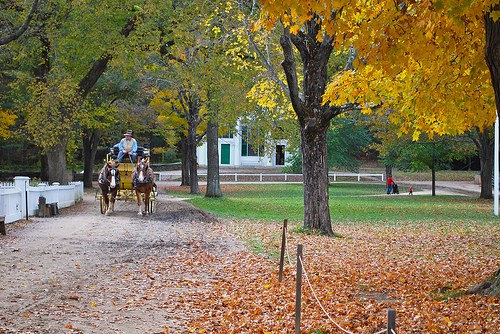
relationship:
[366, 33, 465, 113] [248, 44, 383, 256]
leaves on tree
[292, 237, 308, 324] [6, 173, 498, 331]
pole in ground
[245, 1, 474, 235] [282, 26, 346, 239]
tree has trunk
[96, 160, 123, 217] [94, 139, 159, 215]
horse drawing carriage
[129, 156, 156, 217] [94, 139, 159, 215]
horse drawing carriage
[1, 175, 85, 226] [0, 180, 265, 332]
picket fence beside road